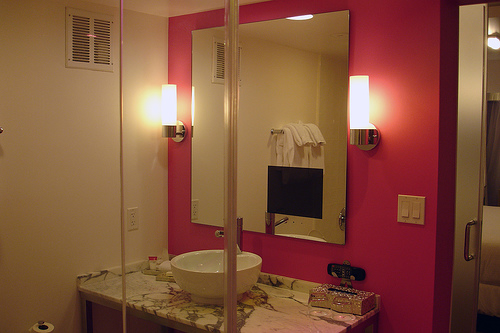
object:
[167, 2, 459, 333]
wall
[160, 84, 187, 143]
light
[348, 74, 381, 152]
light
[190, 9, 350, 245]
mirror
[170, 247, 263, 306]
sink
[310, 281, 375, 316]
kleenex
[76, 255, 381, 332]
counter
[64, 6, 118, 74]
vent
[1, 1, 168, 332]
wall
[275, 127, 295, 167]
towel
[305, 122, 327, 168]
towel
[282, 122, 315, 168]
towel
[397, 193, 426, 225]
light switch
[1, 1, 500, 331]
bathroom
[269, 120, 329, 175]
reflection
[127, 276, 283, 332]
graphics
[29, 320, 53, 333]
toilet paper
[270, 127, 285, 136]
bar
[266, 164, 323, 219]
television screen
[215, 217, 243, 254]
faucet